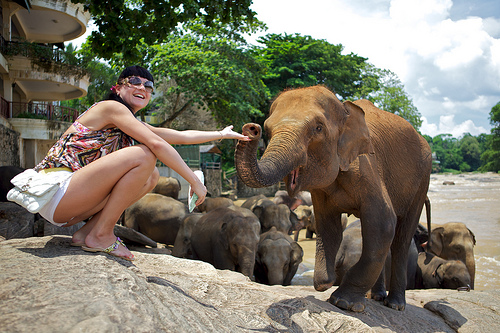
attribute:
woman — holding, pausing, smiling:
[8, 66, 251, 262]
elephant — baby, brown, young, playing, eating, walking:
[235, 83, 435, 313]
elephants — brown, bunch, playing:
[121, 176, 478, 290]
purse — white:
[8, 168, 66, 214]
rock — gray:
[0, 233, 497, 331]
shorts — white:
[30, 168, 71, 229]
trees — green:
[63, 2, 424, 176]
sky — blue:
[243, 0, 499, 140]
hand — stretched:
[218, 125, 250, 144]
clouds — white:
[415, 17, 493, 100]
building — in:
[1, 1, 92, 167]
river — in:
[426, 170, 498, 291]